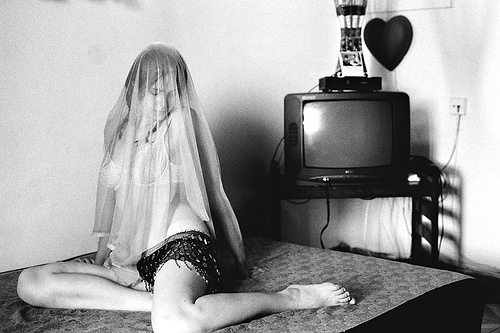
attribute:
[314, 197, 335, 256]
cord — black, electrical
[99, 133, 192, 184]
bra — white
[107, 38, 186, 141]
hair — dark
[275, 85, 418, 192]
tv set — old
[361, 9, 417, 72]
heart — 3-D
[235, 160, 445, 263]
tv stand — black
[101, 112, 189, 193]
bra — white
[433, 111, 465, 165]
cord — wall